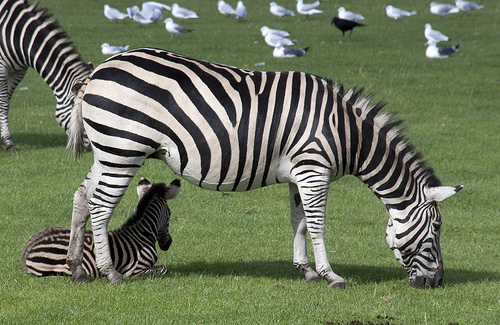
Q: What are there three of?
A: Zebras.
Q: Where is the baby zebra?
A: Next to mom.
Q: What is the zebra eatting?
A: Grass.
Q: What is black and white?
A: Zebras.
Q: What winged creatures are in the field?
A: Birds.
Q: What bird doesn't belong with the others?
A: Black bird.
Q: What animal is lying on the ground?
A: Zebra.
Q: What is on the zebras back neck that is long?
A: Mane.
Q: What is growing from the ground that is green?
A: Grass.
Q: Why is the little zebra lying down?
A: Resting.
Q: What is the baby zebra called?
A: Foal.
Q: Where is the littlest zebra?
A: Under a larger one.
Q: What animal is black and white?
A: Zebra.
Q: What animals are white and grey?
A: Birds.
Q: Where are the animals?
A: In field.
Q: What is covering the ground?
A: Grass.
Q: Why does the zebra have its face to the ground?
A: Grazing.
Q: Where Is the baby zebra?
A: Lying on the ground.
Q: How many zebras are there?
A: Three.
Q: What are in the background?
A: Birds.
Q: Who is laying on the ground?
A: Zebra.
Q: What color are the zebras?
A: Black and white.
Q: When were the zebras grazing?
A: Daytime.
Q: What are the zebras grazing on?
A: Grass.